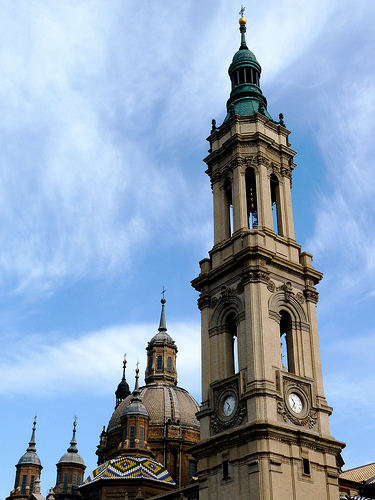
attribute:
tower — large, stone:
[190, 4, 347, 498]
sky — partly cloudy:
[0, 0, 374, 498]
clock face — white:
[282, 388, 311, 422]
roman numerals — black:
[286, 393, 303, 413]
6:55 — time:
[282, 387, 309, 419]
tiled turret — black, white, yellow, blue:
[81, 454, 182, 488]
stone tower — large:
[181, 2, 340, 490]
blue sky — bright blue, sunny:
[3, 7, 365, 378]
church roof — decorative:
[212, 53, 265, 104]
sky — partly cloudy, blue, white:
[3, 4, 366, 270]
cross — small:
[231, 2, 254, 21]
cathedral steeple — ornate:
[227, 46, 272, 105]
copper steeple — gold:
[101, 411, 148, 447]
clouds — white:
[0, 3, 142, 204]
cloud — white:
[174, 2, 314, 123]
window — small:
[295, 455, 319, 478]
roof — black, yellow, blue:
[114, 376, 134, 401]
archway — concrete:
[239, 152, 266, 234]